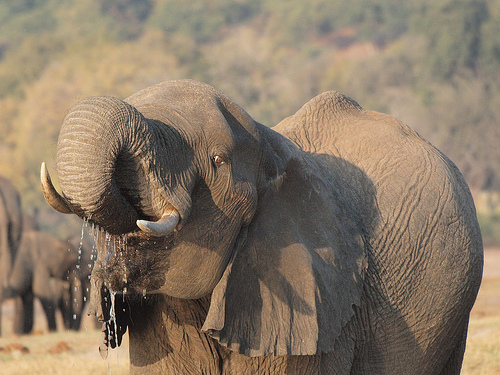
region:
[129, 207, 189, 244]
White ivory elephant tusk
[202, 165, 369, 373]
Large grey elephant ear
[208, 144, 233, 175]
Brown elephant eye looking down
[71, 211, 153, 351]
Water dripping from elephant's trunk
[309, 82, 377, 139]
Hump on back of elephant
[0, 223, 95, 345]
Elephants in the background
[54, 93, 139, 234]
Curved elephant trunk with water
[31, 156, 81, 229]
Curved elephant tusk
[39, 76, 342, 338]
Elephant drinking water from his trunk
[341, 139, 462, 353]
Wrinkled grey elephant skin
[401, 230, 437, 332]
part of a stomach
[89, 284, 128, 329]
part of some water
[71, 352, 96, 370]
part of some dry grass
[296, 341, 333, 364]
edge of an ear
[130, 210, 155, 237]
tip of a tusk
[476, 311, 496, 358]
part of some grass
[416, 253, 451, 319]
part of a stomach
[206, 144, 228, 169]
an elephant's left eye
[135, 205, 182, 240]
an elephant's left tusk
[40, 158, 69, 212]
an elephant's right tusk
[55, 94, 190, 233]
an elephant's grey trunk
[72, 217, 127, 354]
water dripping from an elephant's mouth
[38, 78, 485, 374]
a big elephant drinking water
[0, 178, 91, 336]
a group of elephants in the distance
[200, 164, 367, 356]
an elephant's left ear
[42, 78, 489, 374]
a wrinkled elephant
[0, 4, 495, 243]
a grassy hillside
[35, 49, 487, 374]
elephant in a field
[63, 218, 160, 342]
water elephant is drinking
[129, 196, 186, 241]
left white tusk of an elephant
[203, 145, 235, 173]
left eye of an elephant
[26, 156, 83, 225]
right white tusk of an elephant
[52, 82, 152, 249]
trunk of an elephant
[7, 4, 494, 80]
green trees in the background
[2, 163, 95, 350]
elephants in the grass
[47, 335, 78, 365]
pile of elephant feces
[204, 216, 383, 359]
left ear of an elephant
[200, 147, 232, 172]
the elephants eyes are brown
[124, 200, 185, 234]
the tusks are white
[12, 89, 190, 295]
the trunk is bent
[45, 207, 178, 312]
water is falling out of the elephants mouth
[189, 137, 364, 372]
the elephants ear is big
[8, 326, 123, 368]
the grass is dying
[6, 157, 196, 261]
the elephant has 2 tusks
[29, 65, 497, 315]
the elephant is big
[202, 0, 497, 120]
the trees are in the background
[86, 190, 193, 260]
the tusks are pointy